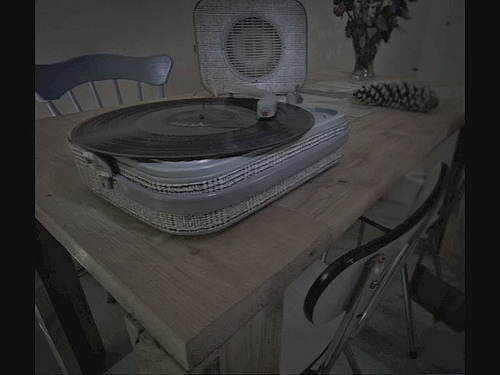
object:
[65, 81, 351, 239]
record player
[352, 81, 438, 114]
cone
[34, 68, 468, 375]
table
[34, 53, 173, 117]
chair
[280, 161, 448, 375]
chair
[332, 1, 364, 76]
plants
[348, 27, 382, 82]
vase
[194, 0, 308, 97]
speaker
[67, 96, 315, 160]
record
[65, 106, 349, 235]
lining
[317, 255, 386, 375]
metal piece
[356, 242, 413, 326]
metal piece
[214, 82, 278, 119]
arm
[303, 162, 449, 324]
trim